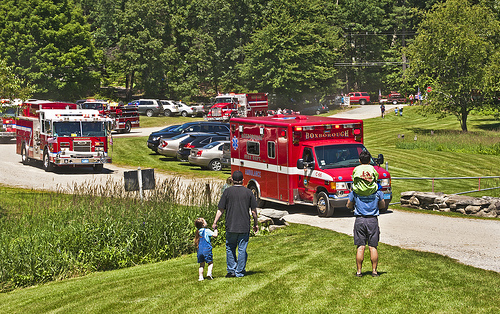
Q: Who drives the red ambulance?
A: Paramedics.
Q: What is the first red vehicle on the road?
A: An ambulance.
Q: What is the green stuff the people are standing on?
A: Grass.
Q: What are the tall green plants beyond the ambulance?
A: Trees.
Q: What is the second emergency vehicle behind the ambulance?
A: A fire truck.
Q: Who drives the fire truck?
A: Fire fighters.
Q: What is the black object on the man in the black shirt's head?
A: A hat.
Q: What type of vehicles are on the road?
A: Emergency vehicles.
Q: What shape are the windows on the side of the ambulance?
A: A rectangle.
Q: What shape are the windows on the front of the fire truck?
A: A rectangle.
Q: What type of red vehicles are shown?
A: Emergency.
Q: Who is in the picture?
A: Men and children.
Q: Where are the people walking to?
A: The road.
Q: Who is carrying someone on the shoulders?
A: Right hand man.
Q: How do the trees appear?
A: Green and lush.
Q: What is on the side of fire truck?
A: White stripe.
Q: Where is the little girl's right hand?
A: In father's hand.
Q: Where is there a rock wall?
A: On side of grass.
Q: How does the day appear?
A: Sunny.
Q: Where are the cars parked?
A: In grass.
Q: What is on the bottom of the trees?
A: Trunks.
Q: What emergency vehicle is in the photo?
A: A fire truck.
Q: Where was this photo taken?
A: A park.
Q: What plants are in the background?
A: Trees.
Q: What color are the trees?
A: Green.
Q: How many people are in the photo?
A: Four.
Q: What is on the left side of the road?
A: A sign.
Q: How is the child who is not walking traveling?
A: On parents shoulders.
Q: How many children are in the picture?
A: Two.